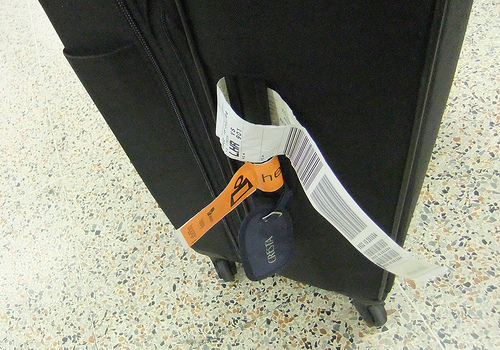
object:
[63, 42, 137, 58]
pocket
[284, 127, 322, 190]
barcode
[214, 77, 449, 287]
label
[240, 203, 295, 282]
tag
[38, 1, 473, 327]
bag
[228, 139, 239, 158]
code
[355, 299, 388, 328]
wheels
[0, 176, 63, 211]
lines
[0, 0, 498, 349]
floor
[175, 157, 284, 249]
yellow tag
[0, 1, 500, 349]
tile floor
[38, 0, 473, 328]
suitcase stand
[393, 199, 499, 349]
flooring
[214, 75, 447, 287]
travel tags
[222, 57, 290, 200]
handle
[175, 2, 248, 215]
zipper